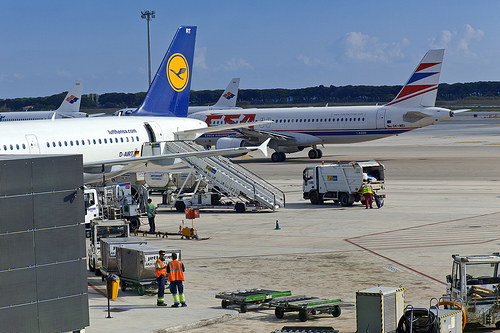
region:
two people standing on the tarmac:
[144, 245, 191, 310]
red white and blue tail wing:
[382, 42, 459, 134]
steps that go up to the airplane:
[161, 135, 286, 210]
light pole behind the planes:
[136, 7, 158, 72]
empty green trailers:
[222, 274, 336, 319]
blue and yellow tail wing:
[143, 13, 203, 120]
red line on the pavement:
[345, 205, 447, 273]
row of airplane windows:
[277, 113, 372, 128]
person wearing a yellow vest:
[356, 176, 373, 196]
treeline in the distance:
[272, 83, 352, 103]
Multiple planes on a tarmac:
[0, 28, 485, 326]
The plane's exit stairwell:
[158, 129, 282, 216]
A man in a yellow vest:
[138, 197, 158, 237]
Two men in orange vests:
[150, 248, 195, 306]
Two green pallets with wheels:
[207, 268, 344, 320]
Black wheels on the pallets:
[272, 305, 305, 317]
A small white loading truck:
[292, 159, 391, 210]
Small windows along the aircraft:
[50, 132, 149, 150]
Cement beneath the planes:
[217, 236, 276, 266]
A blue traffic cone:
[270, 219, 286, 232]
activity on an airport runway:
[3, 6, 488, 322]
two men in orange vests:
[153, 248, 192, 308]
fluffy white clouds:
[303, 25, 493, 71]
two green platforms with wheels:
[213, 282, 348, 323]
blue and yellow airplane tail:
[156, 22, 195, 117]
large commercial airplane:
[196, 77, 461, 153]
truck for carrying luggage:
[299, 157, 389, 209]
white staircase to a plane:
[173, 135, 277, 210]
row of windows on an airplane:
[274, 115, 375, 127]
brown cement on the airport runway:
[393, 151, 495, 212]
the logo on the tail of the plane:
[163, 50, 190, 90]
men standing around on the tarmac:
[147, 250, 185, 307]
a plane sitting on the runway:
[198, 50, 440, 142]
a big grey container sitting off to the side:
[2, 155, 102, 331]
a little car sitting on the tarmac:
[433, 249, 498, 322]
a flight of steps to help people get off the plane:
[161, 135, 279, 214]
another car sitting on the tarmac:
[291, 156, 385, 206]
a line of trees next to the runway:
[241, 79, 497, 103]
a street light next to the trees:
[139, 7, 156, 96]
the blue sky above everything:
[3, 0, 487, 94]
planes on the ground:
[22, 36, 484, 331]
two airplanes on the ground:
[48, 38, 495, 276]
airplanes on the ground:
[11, 52, 478, 260]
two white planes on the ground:
[30, 32, 476, 307]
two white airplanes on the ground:
[14, 25, 491, 282]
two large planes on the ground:
[19, 17, 476, 306]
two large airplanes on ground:
[40, 31, 418, 291]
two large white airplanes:
[28, 22, 494, 278]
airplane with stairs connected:
[93, 90, 375, 281]